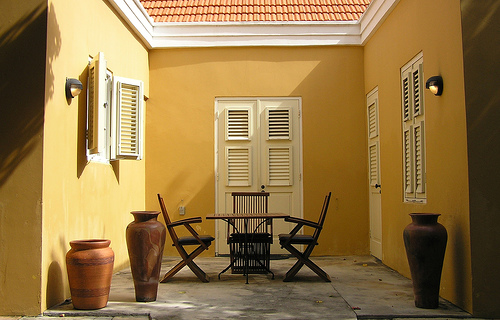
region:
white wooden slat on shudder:
[267, 109, 289, 114]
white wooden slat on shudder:
[266, 113, 291, 119]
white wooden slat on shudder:
[227, 113, 246, 118]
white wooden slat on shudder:
[226, 130, 250, 136]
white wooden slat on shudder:
[120, 90, 138, 95]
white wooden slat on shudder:
[120, 100, 136, 110]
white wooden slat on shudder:
[121, 110, 136, 115]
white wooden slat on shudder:
[120, 120, 135, 130]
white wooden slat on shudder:
[120, 137, 137, 141]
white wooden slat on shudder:
[120, 143, 137, 150]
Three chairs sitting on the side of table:
[40, 35, 455, 312]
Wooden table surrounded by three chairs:
[51, 10, 471, 310]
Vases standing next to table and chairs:
[45, 1, 490, 316]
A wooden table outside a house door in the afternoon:
[51, 5, 461, 310]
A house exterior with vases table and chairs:
[50, 7, 465, 312]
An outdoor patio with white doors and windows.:
[51, 7, 456, 312]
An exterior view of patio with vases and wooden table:
[50, 5, 465, 316]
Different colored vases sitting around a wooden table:
[51, 5, 466, 315]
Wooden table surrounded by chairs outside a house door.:
[50, 5, 470, 315]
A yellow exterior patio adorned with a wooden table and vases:
[57, 11, 479, 311]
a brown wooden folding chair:
[157, 188, 214, 295]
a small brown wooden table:
[212, 201, 280, 273]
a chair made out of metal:
[221, 185, 278, 275]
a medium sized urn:
[54, 221, 118, 319]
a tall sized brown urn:
[124, 203, 182, 314]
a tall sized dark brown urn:
[387, 192, 451, 317]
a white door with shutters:
[208, 85, 320, 245]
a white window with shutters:
[75, 52, 147, 174]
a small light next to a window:
[61, 61, 88, 109]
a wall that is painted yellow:
[312, 45, 366, 212]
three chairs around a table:
[158, 185, 330, 280]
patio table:
[206, 209, 286, 284]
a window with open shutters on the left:
[92, 61, 141, 164]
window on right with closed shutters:
[402, 71, 424, 203]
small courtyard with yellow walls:
[47, 2, 472, 303]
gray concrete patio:
[56, 251, 470, 315]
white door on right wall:
[369, 92, 381, 259]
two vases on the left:
[66, 205, 161, 304]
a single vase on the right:
[400, 213, 447, 306]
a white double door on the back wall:
[213, 98, 303, 252]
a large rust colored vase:
[61, 228, 121, 313]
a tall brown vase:
[123, 197, 169, 309]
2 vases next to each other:
[56, 202, 169, 314]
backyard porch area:
[35, 7, 472, 311]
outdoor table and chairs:
[157, 186, 349, 288]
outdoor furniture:
[153, 180, 348, 292]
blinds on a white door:
[209, 88, 310, 191]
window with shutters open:
[86, 55, 153, 170]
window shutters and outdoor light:
[389, 58, 454, 210]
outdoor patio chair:
[278, 190, 338, 290]